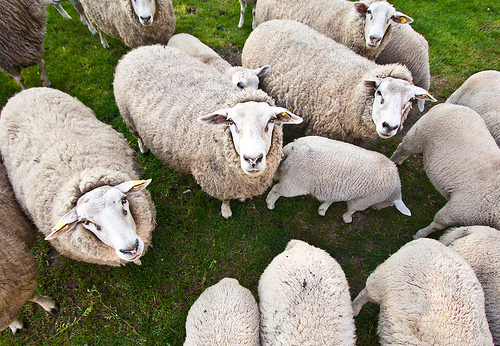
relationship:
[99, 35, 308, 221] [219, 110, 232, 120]
sheep has tag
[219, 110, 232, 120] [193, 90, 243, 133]
tag on ear